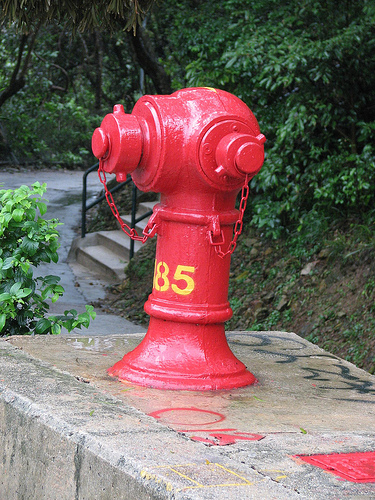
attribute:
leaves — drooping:
[161, 5, 374, 224]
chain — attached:
[97, 159, 151, 242]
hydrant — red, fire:
[91, 86, 268, 387]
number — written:
[176, 264, 195, 296]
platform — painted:
[171, 458, 254, 495]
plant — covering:
[5, 184, 93, 334]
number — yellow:
[128, 249, 197, 307]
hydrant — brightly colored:
[98, 64, 292, 389]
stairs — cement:
[69, 190, 157, 286]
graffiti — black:
[230, 318, 374, 409]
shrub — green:
[0, 181, 102, 337]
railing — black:
[55, 166, 140, 232]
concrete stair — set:
[77, 249, 126, 288]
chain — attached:
[199, 169, 257, 257]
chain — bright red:
[171, 184, 266, 265]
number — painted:
[170, 264, 197, 296]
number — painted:
[150, 262, 171, 292]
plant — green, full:
[0, 178, 95, 337]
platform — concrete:
[1, 329, 373, 494]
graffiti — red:
[146, 403, 266, 446]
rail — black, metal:
[46, 171, 175, 247]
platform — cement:
[3, 305, 371, 497]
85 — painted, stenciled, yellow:
[151, 261, 196, 295]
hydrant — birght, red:
[84, 55, 304, 412]